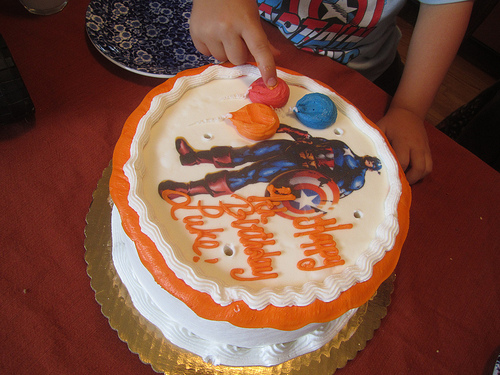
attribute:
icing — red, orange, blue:
[234, 78, 337, 139]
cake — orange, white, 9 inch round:
[108, 63, 414, 364]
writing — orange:
[162, 188, 353, 280]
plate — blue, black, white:
[87, 1, 220, 80]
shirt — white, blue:
[256, 1, 402, 82]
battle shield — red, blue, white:
[267, 171, 336, 217]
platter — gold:
[82, 156, 395, 371]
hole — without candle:
[225, 247, 234, 260]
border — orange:
[110, 62, 412, 331]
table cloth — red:
[1, 0, 498, 372]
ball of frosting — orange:
[235, 104, 279, 138]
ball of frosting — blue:
[295, 93, 336, 129]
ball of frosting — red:
[250, 76, 291, 108]